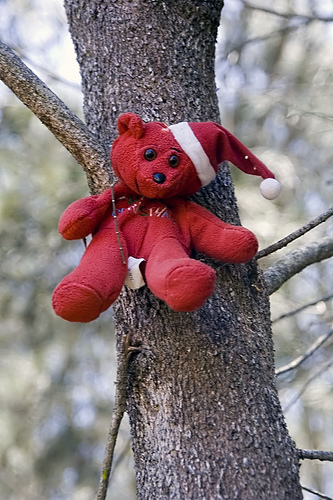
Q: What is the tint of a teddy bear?
A: Dark red.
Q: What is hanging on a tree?
A: Stuffed bear.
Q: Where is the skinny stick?
A: Hanging down from the tree.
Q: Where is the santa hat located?
A: On the side of the head.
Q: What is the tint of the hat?
A: Red and white.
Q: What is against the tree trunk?
A: Red teddy bear.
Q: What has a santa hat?
A: Red teddy bear.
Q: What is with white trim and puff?
A: Santa hat.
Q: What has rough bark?
A: Tree trunk.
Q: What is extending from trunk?
A: Rought tree branch.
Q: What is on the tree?
A: A red bear.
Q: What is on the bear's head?
A: A santa hat.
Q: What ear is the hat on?
A: The bear's left ear.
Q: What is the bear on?
A: A tree.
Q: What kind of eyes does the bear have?
A: Buttons.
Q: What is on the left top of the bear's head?
A: An ear.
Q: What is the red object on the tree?
A: A stuffed bear.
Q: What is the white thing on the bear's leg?
A: A tag.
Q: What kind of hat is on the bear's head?
A: A Santa Claus hat.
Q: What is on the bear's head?
A: A hat.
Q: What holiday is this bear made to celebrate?
A: Christmas.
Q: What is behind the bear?
A: A tree.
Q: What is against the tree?
A: A teddy bear.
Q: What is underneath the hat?
A: A teddy bear.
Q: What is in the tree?
A: A teddy bear.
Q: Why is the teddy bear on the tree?
A: Nailed to the tree.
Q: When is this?
A: Daytime.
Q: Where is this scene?
A: Woods.